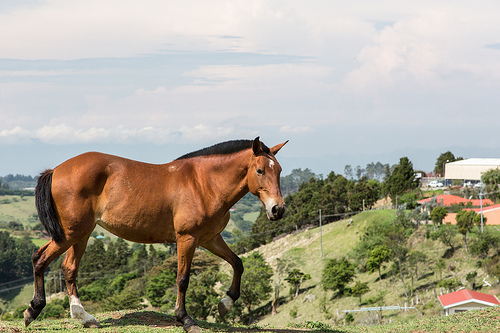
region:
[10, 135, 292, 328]
this is a horse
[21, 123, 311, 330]
the horse is brown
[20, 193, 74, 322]
the leg of a horse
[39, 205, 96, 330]
the leg of a horse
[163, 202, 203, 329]
the leg of a horse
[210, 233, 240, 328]
the leg of a horse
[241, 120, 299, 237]
the head of a horse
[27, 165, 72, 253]
the tail of a horse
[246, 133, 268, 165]
the ear of a horse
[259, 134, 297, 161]
the ear of a horse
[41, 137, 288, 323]
brown horse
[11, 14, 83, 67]
white clouds in blue sky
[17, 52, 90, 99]
white clouds in blue sky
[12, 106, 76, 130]
white clouds in blue sky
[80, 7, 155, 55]
white clouds in blue sky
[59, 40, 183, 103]
white clouds in blue sky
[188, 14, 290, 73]
white clouds in blue sky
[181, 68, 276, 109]
white clouds in blue sky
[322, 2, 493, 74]
white clouds in blue sky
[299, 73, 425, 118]
white clouds in blue sky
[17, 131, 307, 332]
A horse on a hill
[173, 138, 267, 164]
The mane on a horse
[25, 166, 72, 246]
The tail on a horse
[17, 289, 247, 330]
The hooves on a horse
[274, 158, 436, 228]
Trees in the distance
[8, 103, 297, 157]
clouds in the distance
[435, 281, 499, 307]
A red roof on a building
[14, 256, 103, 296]
Power lines and poles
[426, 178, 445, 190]
A vehicle in the distance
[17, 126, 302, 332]
A brown horse with a black tail and mane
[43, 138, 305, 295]
A brown stallion in the field.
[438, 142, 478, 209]
A building on top of the hill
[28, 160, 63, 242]
The horse has a long tail.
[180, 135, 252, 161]
Black hair running down the horse neck.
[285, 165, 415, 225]
Green trees in the valley.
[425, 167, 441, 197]
A white truck parked.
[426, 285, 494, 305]
The roof of the house.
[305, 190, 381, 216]
Electrical wires on poles.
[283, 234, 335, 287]
The grass on the hill.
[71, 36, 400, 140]
The sky is cloudy.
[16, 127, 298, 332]
a brown horse on a field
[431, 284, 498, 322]
a house with red roof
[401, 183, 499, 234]
houses with red roofs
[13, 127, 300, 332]
horse is color brown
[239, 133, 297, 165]
pointy ears of horse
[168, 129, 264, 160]
mane of horse is black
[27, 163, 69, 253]
tail of horse is black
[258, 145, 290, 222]
horse has a white spot on front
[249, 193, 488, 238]
electrical poles near houses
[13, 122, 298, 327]
horse is walking to the right